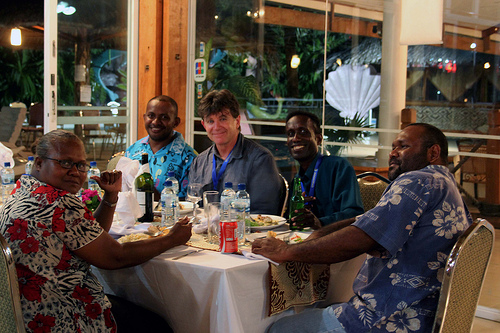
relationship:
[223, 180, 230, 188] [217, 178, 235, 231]
cap on bottle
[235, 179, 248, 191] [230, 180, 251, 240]
cap on bottle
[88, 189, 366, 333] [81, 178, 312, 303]
table on table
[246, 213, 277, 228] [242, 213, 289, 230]
food on plate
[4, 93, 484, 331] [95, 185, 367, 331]
people sitting at table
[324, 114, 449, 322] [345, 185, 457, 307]
man wearing blue shirt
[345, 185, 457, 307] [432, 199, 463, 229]
blue shirt with white flowers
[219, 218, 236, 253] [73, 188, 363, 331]
can on table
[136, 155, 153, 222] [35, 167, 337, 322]
bottle on table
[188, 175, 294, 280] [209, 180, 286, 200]
bottles in caps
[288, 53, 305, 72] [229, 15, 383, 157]
light in window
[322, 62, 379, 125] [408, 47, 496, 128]
decor in window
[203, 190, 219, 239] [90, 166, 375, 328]
glass in table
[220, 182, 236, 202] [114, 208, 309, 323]
bottles in table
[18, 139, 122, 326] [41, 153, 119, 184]
woman in glasses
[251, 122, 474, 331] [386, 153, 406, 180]
man has facial hair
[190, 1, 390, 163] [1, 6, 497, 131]
windows along wall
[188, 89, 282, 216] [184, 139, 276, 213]
male wears shirt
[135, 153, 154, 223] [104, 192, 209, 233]
bottle in middle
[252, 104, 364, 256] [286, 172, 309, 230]
man holds bottle